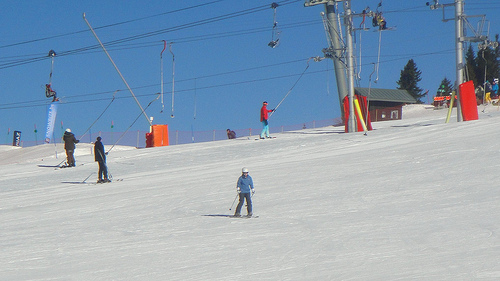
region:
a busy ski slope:
[39, 0, 467, 255]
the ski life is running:
[31, 36, 299, 104]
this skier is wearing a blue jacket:
[226, 169, 268, 224]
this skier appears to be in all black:
[93, 129, 110, 188]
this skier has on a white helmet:
[59, 127, 76, 172]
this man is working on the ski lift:
[249, 45, 315, 140]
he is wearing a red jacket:
[251, 87, 282, 139]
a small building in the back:
[339, 79, 426, 129]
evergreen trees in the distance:
[397, 48, 497, 105]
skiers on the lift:
[43, 71, 65, 109]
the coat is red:
[262, 108, 269, 117]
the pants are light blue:
[262, 125, 269, 133]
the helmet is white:
[240, 164, 250, 175]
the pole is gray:
[277, 83, 286, 116]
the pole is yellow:
[352, 99, 367, 124]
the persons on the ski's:
[228, 165, 258, 222]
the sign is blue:
[46, 110, 56, 126]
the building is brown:
[374, 107, 389, 118]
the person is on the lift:
[41, 80, 61, 104]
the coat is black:
[66, 136, 75, 146]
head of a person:
[241, 165, 251, 175]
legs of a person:
[232, 191, 258, 225]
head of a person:
[260, 99, 270, 105]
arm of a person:
[236, 178, 244, 191]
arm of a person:
[247, 180, 259, 194]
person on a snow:
[85, 129, 118, 182]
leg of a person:
[251, 115, 273, 139]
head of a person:
[60, 118, 75, 133]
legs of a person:
[61, 145, 78, 165]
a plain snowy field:
[295, 185, 448, 257]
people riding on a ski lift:
[27, 4, 497, 109]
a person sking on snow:
[211, 145, 280, 224]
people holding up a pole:
[61, 101, 292, 179]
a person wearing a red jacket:
[252, 103, 269, 121]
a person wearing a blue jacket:
[222, 167, 262, 202]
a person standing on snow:
[222, 173, 270, 213]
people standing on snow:
[32, 98, 299, 173]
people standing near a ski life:
[45, 76, 296, 161]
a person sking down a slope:
[224, 157, 292, 252]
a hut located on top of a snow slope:
[361, 83, 427, 140]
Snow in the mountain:
[151, 194, 229, 262]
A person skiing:
[226, 157, 278, 232]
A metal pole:
[448, 18, 470, 73]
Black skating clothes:
[77, 130, 117, 185]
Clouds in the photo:
[189, 14, 265, 79]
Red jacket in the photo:
[259, 99, 271, 120]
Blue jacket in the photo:
[235, 172, 255, 194]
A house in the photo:
[362, 79, 404, 123]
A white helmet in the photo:
[57, 122, 82, 133]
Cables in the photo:
[154, 1, 246, 90]